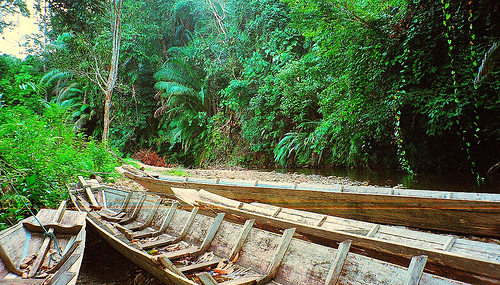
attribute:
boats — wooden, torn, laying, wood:
[71, 163, 493, 279]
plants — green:
[18, 102, 122, 186]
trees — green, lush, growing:
[60, 4, 480, 124]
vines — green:
[390, 49, 496, 138]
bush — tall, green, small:
[392, 13, 498, 194]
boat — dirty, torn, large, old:
[11, 207, 87, 281]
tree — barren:
[84, 16, 153, 135]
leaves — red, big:
[89, 14, 143, 128]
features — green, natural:
[53, 14, 456, 151]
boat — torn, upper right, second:
[172, 178, 390, 239]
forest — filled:
[23, 12, 496, 159]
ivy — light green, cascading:
[389, 87, 411, 183]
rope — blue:
[7, 177, 60, 242]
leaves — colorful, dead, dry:
[191, 256, 231, 283]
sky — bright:
[5, 1, 55, 50]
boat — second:
[90, 179, 192, 263]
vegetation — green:
[15, 136, 122, 191]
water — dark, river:
[335, 161, 495, 197]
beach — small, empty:
[148, 160, 352, 192]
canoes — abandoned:
[78, 169, 497, 279]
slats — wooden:
[156, 203, 179, 230]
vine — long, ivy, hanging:
[382, 76, 479, 172]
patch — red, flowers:
[139, 145, 188, 172]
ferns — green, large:
[266, 126, 330, 175]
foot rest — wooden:
[24, 204, 88, 227]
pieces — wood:
[102, 206, 143, 245]